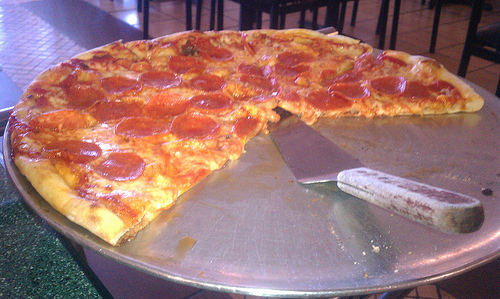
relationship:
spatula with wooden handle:
[269, 109, 488, 241] [345, 166, 486, 242]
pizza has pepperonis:
[25, 43, 481, 216] [171, 67, 368, 114]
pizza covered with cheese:
[25, 43, 481, 216] [113, 54, 417, 113]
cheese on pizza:
[113, 54, 417, 113] [25, 43, 481, 216]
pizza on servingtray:
[25, 43, 481, 216] [129, 121, 496, 285]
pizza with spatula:
[25, 43, 481, 216] [269, 109, 488, 241]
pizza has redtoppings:
[25, 43, 481, 216] [208, 46, 331, 86]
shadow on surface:
[61, 15, 124, 31] [220, 219, 373, 257]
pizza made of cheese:
[25, 43, 481, 216] [113, 54, 417, 113]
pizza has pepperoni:
[25, 43, 481, 216] [221, 54, 373, 94]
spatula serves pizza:
[269, 109, 488, 241] [25, 43, 481, 216]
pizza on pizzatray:
[25, 43, 481, 216] [0, 24, 500, 299]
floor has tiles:
[22, 18, 125, 29] [35, 14, 125, 39]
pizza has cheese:
[25, 43, 481, 216] [113, 54, 417, 113]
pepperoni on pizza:
[221, 54, 373, 94] [25, 43, 481, 216]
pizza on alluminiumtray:
[25, 43, 481, 216] [129, 121, 496, 285]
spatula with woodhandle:
[269, 109, 488, 241] [345, 166, 486, 242]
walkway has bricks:
[29, 24, 85, 43] [34, 26, 126, 33]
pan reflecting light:
[237, 215, 379, 275] [235, 276, 284, 298]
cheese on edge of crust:
[151, 185, 183, 205] [92, 204, 191, 245]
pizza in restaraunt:
[25, 43, 481, 216] [6, 4, 487, 298]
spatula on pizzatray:
[269, 109, 488, 241] [0, 24, 500, 299]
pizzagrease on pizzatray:
[241, 164, 279, 208] [0, 24, 500, 299]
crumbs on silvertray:
[346, 237, 399, 276] [129, 121, 496, 285]